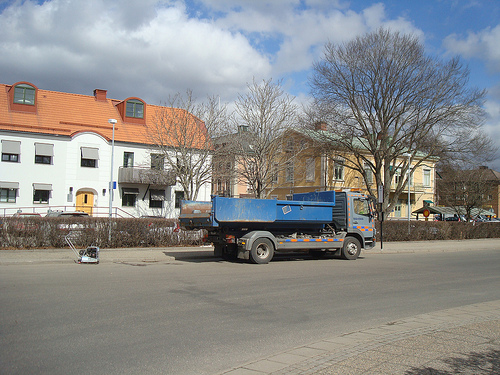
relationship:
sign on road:
[374, 184, 388, 250] [1, 252, 498, 373]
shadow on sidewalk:
[414, 347, 499, 373] [1, 257, 497, 372]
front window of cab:
[355, 199, 371, 217] [335, 180, 380, 258]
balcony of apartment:
[120, 157, 176, 196] [2, 92, 227, 254]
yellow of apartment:
[76, 182, 96, 219] [0, 81, 217, 218]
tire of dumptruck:
[249, 236, 275, 265] [176, 188, 381, 264]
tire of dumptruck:
[338, 234, 363, 259] [176, 188, 381, 264]